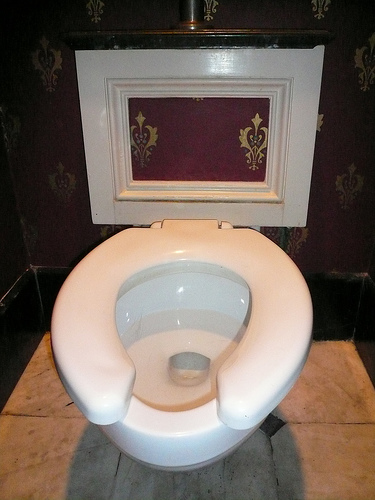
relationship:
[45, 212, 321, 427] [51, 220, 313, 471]
seat on toilet bowl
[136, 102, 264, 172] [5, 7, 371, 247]
wallpaper on wall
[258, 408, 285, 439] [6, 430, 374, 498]
damage on floor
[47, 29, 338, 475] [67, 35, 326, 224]
toilet has tank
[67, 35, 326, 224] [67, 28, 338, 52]
tank has blacklid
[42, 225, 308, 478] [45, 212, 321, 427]
toilet has seat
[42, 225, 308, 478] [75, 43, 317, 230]
toilet has frame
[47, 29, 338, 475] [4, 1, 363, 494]
toilet in bathroom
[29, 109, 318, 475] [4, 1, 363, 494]
toilet in bathroom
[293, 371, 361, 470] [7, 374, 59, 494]
tile on floor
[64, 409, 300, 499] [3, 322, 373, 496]
shadow on ground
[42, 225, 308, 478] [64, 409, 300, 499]
toilet has shadow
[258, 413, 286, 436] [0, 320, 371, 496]
spot on tile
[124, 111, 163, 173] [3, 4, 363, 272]
design on wall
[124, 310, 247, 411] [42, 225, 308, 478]
water in toilet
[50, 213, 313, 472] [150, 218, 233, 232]
toliet has hinge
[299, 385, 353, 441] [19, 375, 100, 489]
tile on floor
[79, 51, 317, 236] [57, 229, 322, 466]
picture in back to toilet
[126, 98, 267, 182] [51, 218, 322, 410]
wallpaper in middle of toilet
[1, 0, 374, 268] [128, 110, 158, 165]
wallpaper has design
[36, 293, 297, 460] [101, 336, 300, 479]
light reflecting on toilet bowl